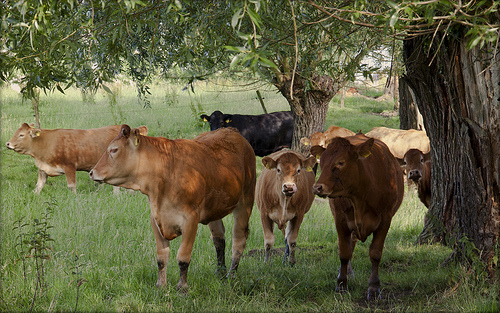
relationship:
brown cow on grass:
[307, 130, 406, 300] [2, 86, 487, 303]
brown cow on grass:
[256, 147, 318, 267] [2, 86, 487, 303]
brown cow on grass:
[88, 124, 257, 292] [2, 86, 487, 303]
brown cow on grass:
[5, 119, 147, 198] [2, 86, 487, 303]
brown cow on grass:
[256, 147, 318, 267] [60, 190, 340, 301]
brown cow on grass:
[307, 130, 406, 300] [60, 190, 340, 301]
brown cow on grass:
[88, 124, 257, 292] [60, 190, 340, 301]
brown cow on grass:
[5, 119, 147, 198] [60, 190, 340, 301]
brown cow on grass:
[394, 147, 432, 207] [60, 190, 340, 301]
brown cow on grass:
[5, 119, 147, 198] [31, 207, 198, 304]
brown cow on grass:
[88, 124, 257, 292] [31, 207, 198, 304]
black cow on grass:
[200, 110, 318, 177] [31, 207, 198, 304]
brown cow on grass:
[256, 147, 318, 267] [31, 207, 198, 304]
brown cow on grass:
[307, 130, 406, 300] [31, 207, 198, 304]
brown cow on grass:
[394, 147, 432, 207] [31, 207, 198, 304]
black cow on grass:
[203, 107, 302, 148] [81, 198, 143, 262]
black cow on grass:
[200, 110, 318, 177] [2, 86, 487, 303]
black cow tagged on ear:
[200, 110, 318, 177] [220, 111, 242, 132]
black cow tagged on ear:
[200, 110, 318, 177] [200, 113, 205, 139]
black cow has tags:
[200, 110, 318, 177] [196, 113, 235, 128]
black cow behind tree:
[200, 110, 318, 177] [0, 0, 415, 138]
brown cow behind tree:
[88, 124, 257, 292] [2, 0, 425, 164]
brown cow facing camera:
[256, 147, 318, 267] [187, 117, 447, 297]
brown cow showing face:
[88, 124, 257, 292] [84, 125, 268, 287]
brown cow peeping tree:
[394, 147, 432, 207] [387, 10, 497, 275]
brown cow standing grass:
[5, 119, 147, 198] [20, 198, 150, 290]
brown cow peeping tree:
[394, 147, 432, 207] [427, 50, 484, 174]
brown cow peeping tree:
[307, 130, 406, 300] [419, 18, 485, 75]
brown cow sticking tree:
[394, 147, 432, 207] [387, 10, 497, 275]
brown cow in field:
[307, 130, 406, 300] [0, 73, 498, 310]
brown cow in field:
[256, 147, 318, 267] [0, 73, 498, 310]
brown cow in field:
[88, 124, 257, 292] [0, 73, 498, 310]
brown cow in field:
[5, 119, 147, 198] [0, 73, 498, 310]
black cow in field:
[200, 110, 318, 177] [0, 73, 498, 310]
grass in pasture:
[41, 219, 142, 286] [4, 77, 466, 304]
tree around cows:
[212, 12, 389, 202] [82, 53, 437, 279]